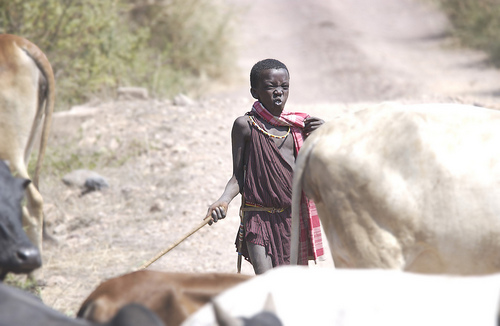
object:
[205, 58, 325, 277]
child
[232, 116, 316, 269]
clothes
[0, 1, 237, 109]
grass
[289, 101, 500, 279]
animal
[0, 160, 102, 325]
cow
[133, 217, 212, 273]
stick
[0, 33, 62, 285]
cow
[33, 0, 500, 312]
road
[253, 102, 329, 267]
scarf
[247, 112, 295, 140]
necklace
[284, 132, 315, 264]
tail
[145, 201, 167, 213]
rocks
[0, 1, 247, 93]
bush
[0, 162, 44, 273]
face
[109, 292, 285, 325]
cow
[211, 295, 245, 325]
horns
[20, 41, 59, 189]
tail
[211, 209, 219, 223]
fingers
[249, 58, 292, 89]
hair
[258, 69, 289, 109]
face